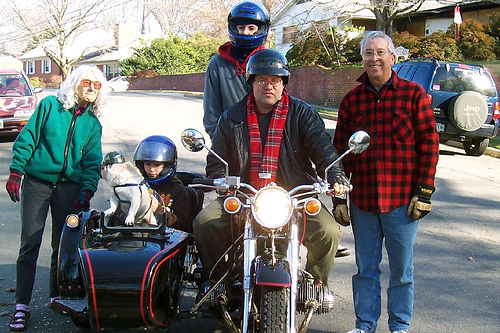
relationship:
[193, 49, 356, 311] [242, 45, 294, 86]
man wearing helmet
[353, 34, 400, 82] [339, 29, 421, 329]
head of person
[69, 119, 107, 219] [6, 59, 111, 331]
arm of person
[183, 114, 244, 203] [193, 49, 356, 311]
arm of man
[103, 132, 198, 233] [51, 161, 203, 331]
person sitting in side car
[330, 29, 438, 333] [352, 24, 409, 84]
man has head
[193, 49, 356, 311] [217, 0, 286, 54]
man has head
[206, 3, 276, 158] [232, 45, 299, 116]
person has head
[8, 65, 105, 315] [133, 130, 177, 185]
person has head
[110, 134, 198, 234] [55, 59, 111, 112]
person has head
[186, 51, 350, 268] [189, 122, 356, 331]
man sitting on motorbike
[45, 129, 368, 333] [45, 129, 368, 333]
cycle attached to cycle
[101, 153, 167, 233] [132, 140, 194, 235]
dog sitting with person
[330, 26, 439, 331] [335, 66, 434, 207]
man dressed in shirt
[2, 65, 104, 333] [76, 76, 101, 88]
person wearing sunglasses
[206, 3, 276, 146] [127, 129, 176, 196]
person wearing helmet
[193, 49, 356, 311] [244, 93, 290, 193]
man wearing redscarf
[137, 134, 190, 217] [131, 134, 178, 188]
boy wearing helmet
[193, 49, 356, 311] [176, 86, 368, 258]
man wearing jacket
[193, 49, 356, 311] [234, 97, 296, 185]
man wearing redscarf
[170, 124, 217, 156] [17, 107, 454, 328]
mirror on cycle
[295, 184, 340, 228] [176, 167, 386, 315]
light on cycle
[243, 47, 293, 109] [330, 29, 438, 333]
head of man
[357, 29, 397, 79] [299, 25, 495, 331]
head of a person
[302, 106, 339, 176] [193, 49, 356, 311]
arm of a man